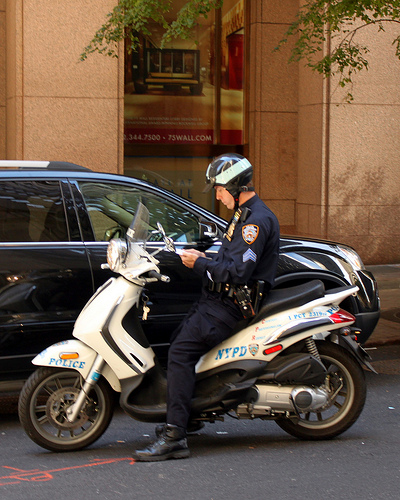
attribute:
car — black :
[0, 161, 377, 411]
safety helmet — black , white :
[197, 156, 257, 201]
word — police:
[46, 355, 86, 371]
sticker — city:
[204, 339, 280, 365]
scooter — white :
[28, 240, 386, 448]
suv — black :
[0, 157, 382, 407]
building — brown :
[3, 2, 395, 254]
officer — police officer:
[99, 147, 363, 390]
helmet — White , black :
[193, 148, 253, 200]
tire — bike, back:
[258, 335, 378, 431]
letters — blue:
[206, 337, 248, 359]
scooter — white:
[10, 192, 373, 456]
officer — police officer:
[2, 143, 377, 458]